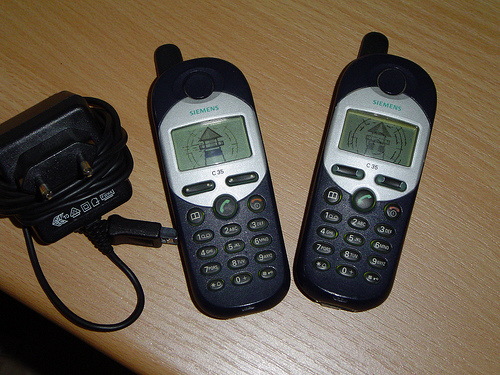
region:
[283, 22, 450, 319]
A black cell phone.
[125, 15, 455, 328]
Two black cell phones.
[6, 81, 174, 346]
A cell phone charger.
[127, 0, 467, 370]
The cell phones are sitting on a wood table.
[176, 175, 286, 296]
Buttons on a cell phone.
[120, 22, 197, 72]
The antenna on a cell phone.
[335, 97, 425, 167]
The screen on a cell phone.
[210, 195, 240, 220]
The call button on a cell phone.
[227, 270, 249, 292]
The 0 button on a cell phone.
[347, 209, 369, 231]
The 2 button on a cell phone.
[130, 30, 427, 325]
2 phones are pictured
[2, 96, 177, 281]
the charger is black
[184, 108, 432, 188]
triangles are on the screens of phones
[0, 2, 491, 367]
the table is made of wood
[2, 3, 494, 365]
the table is brown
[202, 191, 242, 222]
the button is green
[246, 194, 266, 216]
the button is red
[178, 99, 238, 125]
the letters are green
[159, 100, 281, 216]
the top part of phone is gray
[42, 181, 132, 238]
white symbols on black charger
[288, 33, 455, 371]
a black cellphone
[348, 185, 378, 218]
call button on a cell phone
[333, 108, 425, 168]
display screen on cell phone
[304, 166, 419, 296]
control buttons on a cellphone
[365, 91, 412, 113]
company logo on cell phone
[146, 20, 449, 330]
two cellphones laying on a desk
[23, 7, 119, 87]
brown wooden desktop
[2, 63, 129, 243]
a black phone charger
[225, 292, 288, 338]
charging port on a cellphone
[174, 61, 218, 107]
speaker on cellphone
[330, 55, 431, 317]
black and gray radio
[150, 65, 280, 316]
black and gray radio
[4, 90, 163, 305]
black colored radio charger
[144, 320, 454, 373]
brown colored wooden table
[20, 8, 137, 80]
brown colored wooden table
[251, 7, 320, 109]
brown colored wooden table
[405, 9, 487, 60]
brown colored wooden table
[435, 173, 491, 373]
brown colored wooden table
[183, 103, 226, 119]
green colored logo on radio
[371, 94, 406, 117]
green colored logo on radio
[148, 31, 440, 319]
Two identical cell phones.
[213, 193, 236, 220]
Middle button on the left phone with a green phone on it.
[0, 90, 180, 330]
Large black charger with usb on the end.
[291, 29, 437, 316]
Black cell phone on the right of the table.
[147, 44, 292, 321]
Left side cell phone.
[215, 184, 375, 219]
Two middle black buttons on the cell phones with green phones on them.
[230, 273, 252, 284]
0 on a button on the left phone.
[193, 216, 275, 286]
All the buttons with numbers on the left side phone.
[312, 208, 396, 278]
All the buttons with numbers on them on the right side phone.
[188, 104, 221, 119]
The word SIEMENS on a left side phone.